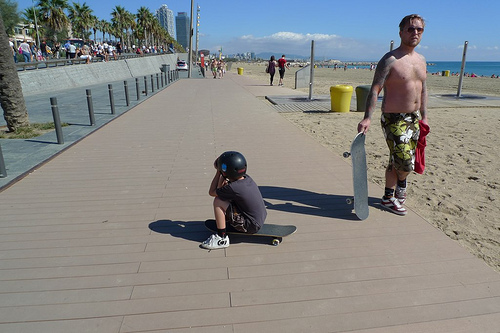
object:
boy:
[198, 151, 266, 250]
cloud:
[214, 32, 347, 55]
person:
[276, 53, 290, 85]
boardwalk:
[7, 57, 499, 333]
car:
[176, 60, 188, 71]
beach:
[209, 61, 499, 274]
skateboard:
[203, 219, 298, 246]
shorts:
[379, 110, 421, 172]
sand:
[428, 102, 498, 222]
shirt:
[410, 117, 430, 174]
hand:
[419, 118, 428, 125]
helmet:
[214, 150, 248, 183]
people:
[432, 68, 498, 79]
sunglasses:
[400, 28, 425, 33]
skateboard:
[342, 131, 368, 220]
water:
[467, 57, 493, 74]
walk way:
[0, 67, 499, 333]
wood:
[46, 183, 168, 250]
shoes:
[380, 188, 408, 216]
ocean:
[427, 59, 499, 76]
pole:
[48, 97, 65, 144]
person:
[265, 55, 279, 86]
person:
[53, 41, 61, 59]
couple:
[266, 54, 290, 87]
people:
[62, 37, 123, 64]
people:
[8, 39, 61, 64]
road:
[14, 50, 155, 74]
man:
[356, 13, 429, 216]